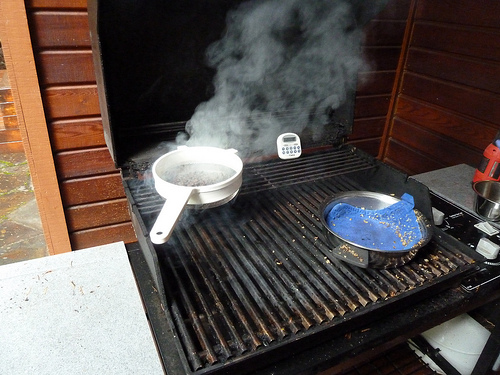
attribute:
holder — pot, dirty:
[330, 191, 425, 251]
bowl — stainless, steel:
[322, 190, 430, 254]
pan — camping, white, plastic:
[139, 134, 235, 241]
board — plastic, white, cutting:
[0, 230, 171, 374]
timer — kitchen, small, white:
[275, 131, 300, 155]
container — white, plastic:
[417, 309, 498, 367]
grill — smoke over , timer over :
[129, 125, 466, 373]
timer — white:
[268, 125, 308, 157]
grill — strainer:
[128, 105, 469, 359]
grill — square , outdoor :
[123, 120, 498, 368]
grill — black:
[90, 115, 490, 367]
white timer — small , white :
[269, 130, 307, 163]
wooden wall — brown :
[1, 10, 498, 245]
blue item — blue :
[327, 194, 424, 255]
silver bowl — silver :
[465, 166, 497, 224]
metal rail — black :
[163, 246, 244, 359]